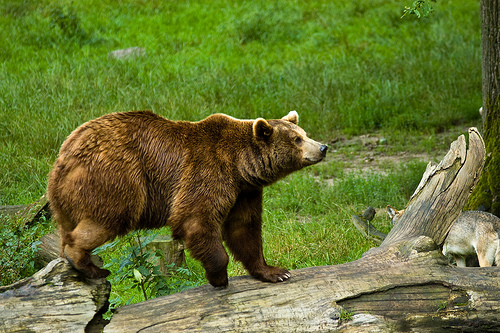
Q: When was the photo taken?
A: Daytime.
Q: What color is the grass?
A: Green.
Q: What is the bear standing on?
A: A log.